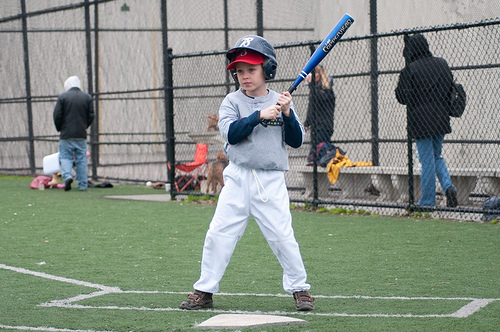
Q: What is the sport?
A: Baseball.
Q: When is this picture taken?
A: Daytime.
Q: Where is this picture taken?
A: At the field.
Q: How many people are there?
A: Four.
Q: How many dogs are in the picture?
A: One.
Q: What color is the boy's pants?
A: White.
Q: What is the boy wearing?
A: Cap and helmet.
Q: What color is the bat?
A: Blue.